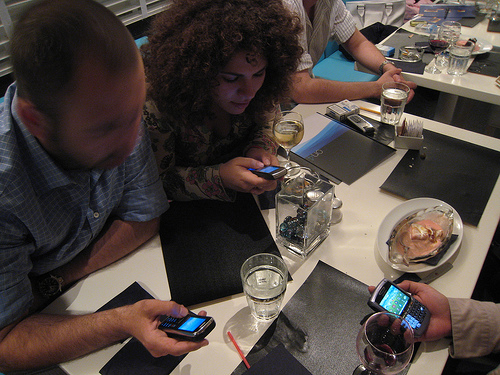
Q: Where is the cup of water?
A: On the table.